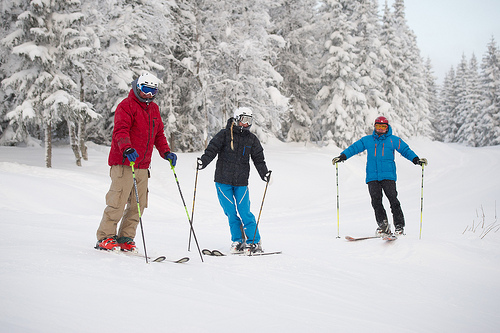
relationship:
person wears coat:
[338, 116, 425, 230] [340, 131, 415, 182]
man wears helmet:
[96, 73, 174, 252] [139, 71, 161, 90]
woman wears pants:
[195, 109, 273, 254] [215, 181, 260, 244]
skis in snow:
[334, 155, 425, 236] [1, 149, 497, 330]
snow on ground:
[1, 149, 497, 330] [9, 168, 93, 332]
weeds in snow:
[463, 205, 499, 242] [1, 149, 497, 330]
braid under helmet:
[225, 122, 235, 149] [235, 109, 254, 121]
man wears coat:
[96, 73, 174, 252] [109, 89, 171, 163]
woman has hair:
[195, 109, 273, 254] [229, 123, 236, 150]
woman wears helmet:
[195, 109, 273, 254] [235, 109, 254, 121]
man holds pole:
[96, 73, 174, 252] [125, 155, 147, 261]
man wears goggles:
[96, 73, 174, 252] [140, 86, 155, 94]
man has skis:
[96, 73, 174, 252] [130, 153, 206, 263]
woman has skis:
[195, 109, 273, 254] [190, 161, 268, 260]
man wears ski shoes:
[96, 73, 174, 252] [100, 234, 139, 250]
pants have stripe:
[215, 181, 260, 244] [217, 184, 249, 201]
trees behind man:
[3, 6, 498, 141] [85, 65, 182, 260]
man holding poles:
[85, 65, 182, 260] [111, 151, 430, 260]